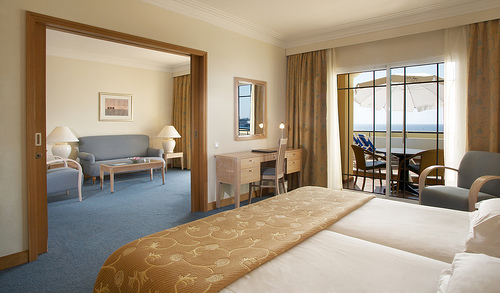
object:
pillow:
[464, 198, 500, 258]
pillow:
[438, 253, 500, 293]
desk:
[214, 148, 304, 209]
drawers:
[238, 157, 261, 184]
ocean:
[352, 122, 442, 133]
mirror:
[237, 82, 256, 136]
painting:
[98, 92, 134, 122]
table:
[163, 152, 184, 172]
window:
[336, 62, 444, 201]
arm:
[466, 175, 500, 212]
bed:
[94, 185, 500, 293]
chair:
[418, 151, 500, 212]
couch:
[78, 134, 165, 186]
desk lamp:
[279, 122, 286, 139]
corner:
[227, 33, 314, 131]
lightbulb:
[278, 122, 284, 129]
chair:
[249, 138, 289, 205]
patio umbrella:
[354, 74, 444, 113]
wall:
[0, 0, 500, 270]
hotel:
[0, 0, 500, 293]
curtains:
[285, 20, 497, 191]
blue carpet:
[0, 167, 274, 293]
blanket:
[92, 185, 376, 292]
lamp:
[46, 125, 79, 160]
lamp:
[157, 125, 182, 153]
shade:
[69, 128, 84, 161]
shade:
[157, 125, 182, 137]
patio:
[352, 130, 444, 201]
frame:
[232, 76, 267, 141]